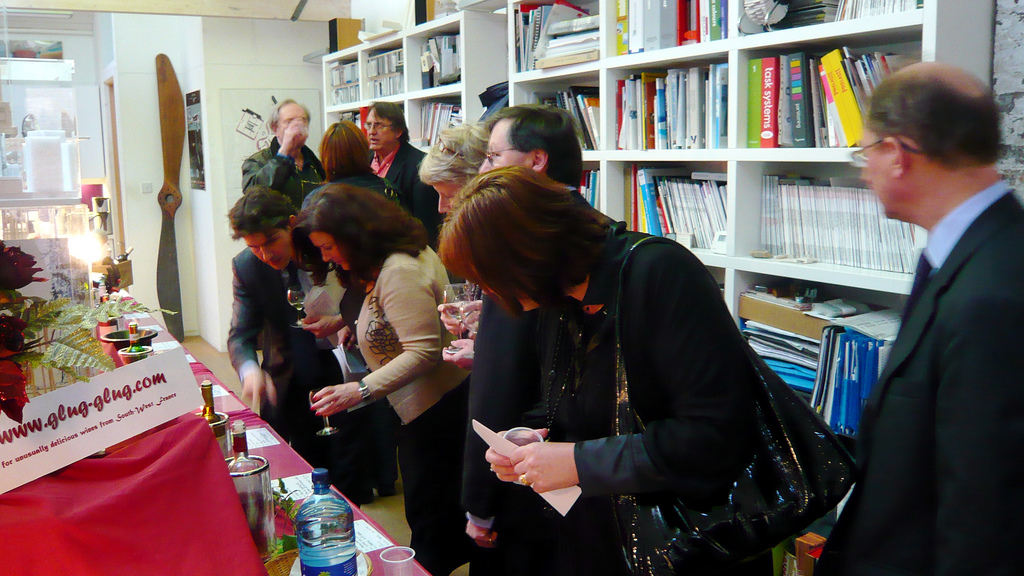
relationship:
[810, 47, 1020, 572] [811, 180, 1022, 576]
man in man suit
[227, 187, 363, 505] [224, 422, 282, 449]
man pointing at paper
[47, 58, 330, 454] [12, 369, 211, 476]
sign with address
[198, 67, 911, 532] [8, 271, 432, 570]
people standing around table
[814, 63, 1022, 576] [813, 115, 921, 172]
man wearing glasses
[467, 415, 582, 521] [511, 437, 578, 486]
white paper in hand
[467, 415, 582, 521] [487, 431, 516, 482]
white paper in hand